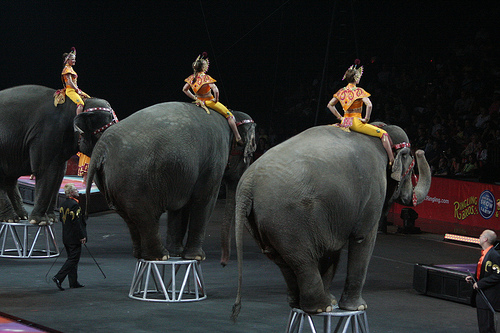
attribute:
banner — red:
[391, 177, 499, 231]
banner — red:
[388, 175, 499, 235]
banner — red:
[384, 170, 499, 238]